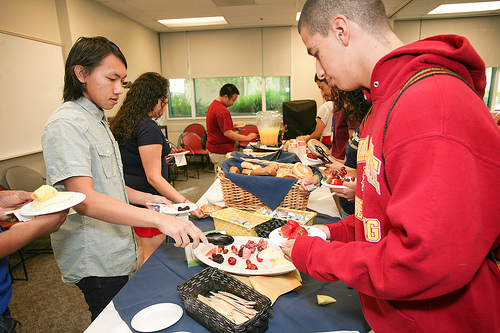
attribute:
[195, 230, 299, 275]
plate fruits — on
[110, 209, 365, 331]
tablecloth — blue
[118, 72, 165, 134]
hair — dark, curly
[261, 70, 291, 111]
window — pictured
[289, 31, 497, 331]
t shirt — is on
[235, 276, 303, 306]
cloth — pictured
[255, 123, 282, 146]
juice — orange juice, fresh, rich in vitamin C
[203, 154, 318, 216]
basket — has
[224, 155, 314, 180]
bread — in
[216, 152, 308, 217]
basket — with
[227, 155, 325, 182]
bagels — bread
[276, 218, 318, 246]
strawberries — Large, red, luscious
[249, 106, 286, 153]
juicer — has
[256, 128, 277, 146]
fruit juice — in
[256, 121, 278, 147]
juice — orange juice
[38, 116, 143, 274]
shirt — light blue, short sleeved, button down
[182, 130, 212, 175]
red chair — by the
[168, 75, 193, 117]
window — has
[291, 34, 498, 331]
hoodie — red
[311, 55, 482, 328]
sweatshirt — red, hooded, lettered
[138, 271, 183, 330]
table — with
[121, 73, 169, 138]
hair — long, curly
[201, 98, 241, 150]
shirt — short sleeve, red, tee shirt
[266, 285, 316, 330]
table — pictured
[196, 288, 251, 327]
spoons — in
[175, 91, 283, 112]
greens — by the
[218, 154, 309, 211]
basket — wicker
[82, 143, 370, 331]
table — pictured